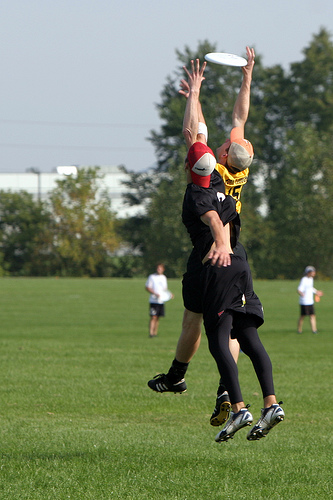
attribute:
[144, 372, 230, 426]
cleats — white, black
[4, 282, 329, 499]
grass — short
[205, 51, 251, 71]
frisbee — white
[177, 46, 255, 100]
hands — above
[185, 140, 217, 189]
cap — red, white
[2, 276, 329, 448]
grass — green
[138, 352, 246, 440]
cleats — black, Adidas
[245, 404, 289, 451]
cleats — black, white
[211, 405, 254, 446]
cleats — black